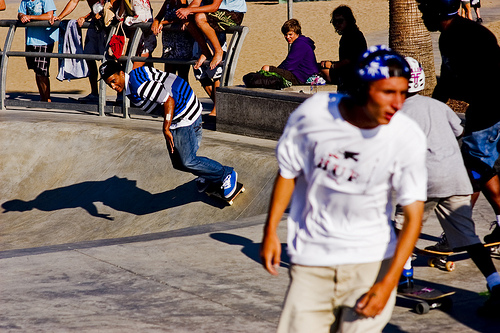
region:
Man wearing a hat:
[342, 38, 417, 118]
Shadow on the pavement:
[33, 138, 160, 209]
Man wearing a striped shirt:
[104, 53, 251, 174]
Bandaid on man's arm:
[152, 105, 179, 130]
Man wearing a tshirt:
[271, 88, 490, 313]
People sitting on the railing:
[17, 3, 239, 91]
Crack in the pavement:
[82, 243, 192, 330]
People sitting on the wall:
[275, 10, 382, 163]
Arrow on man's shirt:
[327, 123, 384, 190]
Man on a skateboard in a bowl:
[94, 58, 252, 208]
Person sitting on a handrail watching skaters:
[175, 0, 249, 67]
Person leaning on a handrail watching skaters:
[16, 0, 56, 105]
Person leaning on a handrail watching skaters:
[65, 0, 105, 100]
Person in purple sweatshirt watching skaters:
[258, 15, 320, 90]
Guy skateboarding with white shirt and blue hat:
[258, 42, 433, 332]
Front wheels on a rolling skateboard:
[426, 257, 458, 274]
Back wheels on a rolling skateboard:
[412, 291, 457, 312]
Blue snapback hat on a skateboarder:
[347, 38, 417, 87]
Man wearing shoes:
[187, 165, 249, 200]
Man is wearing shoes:
[191, 166, 238, 200]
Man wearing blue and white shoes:
[194, 162, 240, 201]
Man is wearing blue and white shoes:
[190, 165, 237, 200]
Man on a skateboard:
[189, 169, 245, 198]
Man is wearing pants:
[161, 108, 232, 185]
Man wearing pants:
[160, 121, 233, 187]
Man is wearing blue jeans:
[165, 113, 233, 182]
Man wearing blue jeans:
[163, 108, 233, 182]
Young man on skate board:
[85, 55, 250, 207]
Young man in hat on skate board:
[93, 53, 245, 208]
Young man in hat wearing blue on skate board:
[88, 54, 248, 206]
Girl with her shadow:
[257, 2, 359, 85]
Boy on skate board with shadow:
[0, 58, 247, 219]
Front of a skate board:
[400, 274, 456, 319]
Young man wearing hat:
[336, 38, 406, 128]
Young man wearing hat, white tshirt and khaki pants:
[250, 38, 468, 332]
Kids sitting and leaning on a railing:
[12, 0, 247, 125]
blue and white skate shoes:
[219, 170, 237, 200]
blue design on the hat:
[353, 45, 409, 80]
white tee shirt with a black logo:
[275, 91, 427, 264]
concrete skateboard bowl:
[1, 107, 286, 252]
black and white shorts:
[24, 40, 52, 71]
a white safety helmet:
[401, 58, 426, 92]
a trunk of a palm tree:
[386, 0, 436, 89]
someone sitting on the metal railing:
[191, 0, 243, 71]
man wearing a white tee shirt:
[273, 85, 424, 265]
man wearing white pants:
[272, 251, 391, 328]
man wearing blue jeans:
[148, 111, 226, 178]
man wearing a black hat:
[89, 56, 121, 86]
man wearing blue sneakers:
[187, 165, 241, 200]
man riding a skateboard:
[86, 53, 246, 221]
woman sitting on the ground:
[258, 15, 320, 95]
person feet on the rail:
[192, 47, 232, 69]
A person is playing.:
[264, 55, 421, 327]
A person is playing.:
[376, 54, 492, 306]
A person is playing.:
[418, 5, 498, 226]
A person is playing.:
[81, 55, 256, 205]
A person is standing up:
[85, 0, 119, 105]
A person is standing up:
[119, 4, 159, 63]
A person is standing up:
[166, 0, 201, 93]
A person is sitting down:
[193, 4, 268, 91]